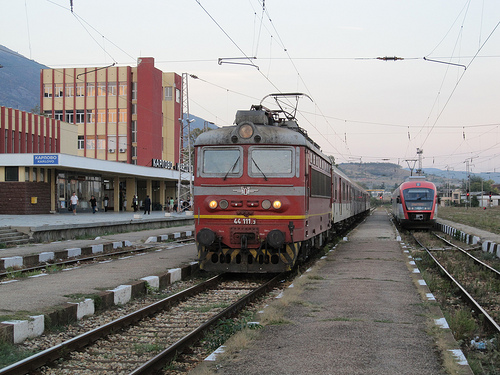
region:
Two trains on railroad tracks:
[167, 82, 467, 300]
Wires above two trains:
[186, 0, 483, 152]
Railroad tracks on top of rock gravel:
[26, 273, 305, 371]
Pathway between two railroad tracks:
[334, 168, 405, 370]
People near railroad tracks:
[0, 150, 215, 235]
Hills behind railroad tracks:
[310, 135, 477, 192]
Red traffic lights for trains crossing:
[447, 147, 497, 219]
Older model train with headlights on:
[163, 89, 378, 297]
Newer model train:
[377, 110, 464, 291]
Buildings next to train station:
[3, 56, 272, 325]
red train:
[197, 79, 357, 261]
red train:
[380, 164, 442, 234]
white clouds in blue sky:
[20, 6, 85, 40]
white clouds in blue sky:
[80, 6, 147, 53]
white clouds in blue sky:
[152, 15, 214, 59]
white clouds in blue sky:
[235, 1, 296, 52]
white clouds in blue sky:
[304, 6, 359, 61]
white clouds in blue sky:
[360, 25, 432, 110]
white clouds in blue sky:
[314, 43, 368, 124]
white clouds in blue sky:
[404, 109, 429, 146]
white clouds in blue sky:
[325, 36, 352, 51]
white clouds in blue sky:
[392, 62, 463, 84]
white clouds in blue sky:
[411, 15, 453, 67]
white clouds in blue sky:
[340, 49, 395, 99]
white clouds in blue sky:
[390, 118, 460, 153]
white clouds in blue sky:
[170, 18, 232, 53]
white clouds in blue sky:
[334, 18, 418, 66]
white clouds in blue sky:
[395, 69, 443, 119]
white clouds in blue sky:
[304, 58, 354, 109]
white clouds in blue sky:
[191, 11, 249, 45]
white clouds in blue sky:
[52, 15, 109, 45]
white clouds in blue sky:
[378, 79, 409, 101]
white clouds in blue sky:
[425, 46, 470, 111]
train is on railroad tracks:
[192, 92, 377, 282]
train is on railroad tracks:
[393, 171, 442, 228]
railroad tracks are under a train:
[413, 218, 498, 329]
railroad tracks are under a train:
[3, 274, 293, 374]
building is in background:
[3, 56, 188, 214]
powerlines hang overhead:
[20, 2, 497, 203]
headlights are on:
[205, 195, 285, 212]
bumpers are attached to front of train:
[193, 225, 288, 252]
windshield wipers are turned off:
[220, 156, 267, 181]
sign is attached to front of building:
[150, 156, 194, 172]